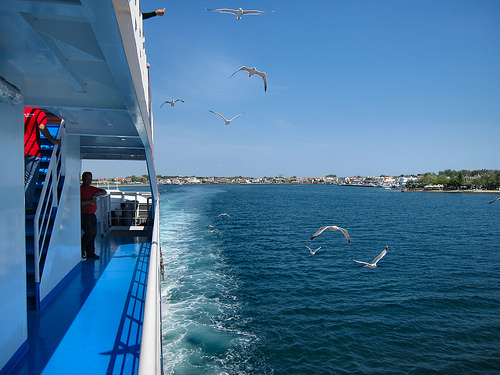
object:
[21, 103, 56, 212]
man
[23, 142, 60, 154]
steps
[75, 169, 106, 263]
man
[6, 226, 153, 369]
deck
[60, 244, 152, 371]
floor